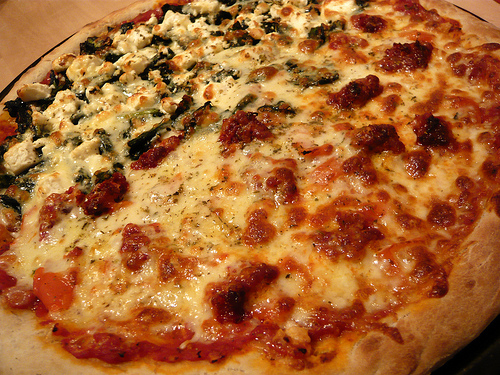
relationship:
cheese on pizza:
[382, 65, 453, 186] [41, 23, 478, 363]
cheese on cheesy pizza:
[0, 0, 500, 375] [0, 0, 500, 375]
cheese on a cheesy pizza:
[0, 0, 500, 375] [0, 0, 500, 375]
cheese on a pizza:
[0, 0, 500, 375] [41, 23, 478, 363]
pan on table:
[4, 74, 46, 84] [3, 8, 44, 33]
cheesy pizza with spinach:
[0, 0, 500, 375] [73, 27, 215, 147]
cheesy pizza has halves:
[0, 0, 500, 375] [5, 6, 498, 368]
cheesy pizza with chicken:
[3, 7, 276, 177] [61, 52, 117, 87]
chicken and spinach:
[61, 52, 117, 87] [6, 99, 31, 129]